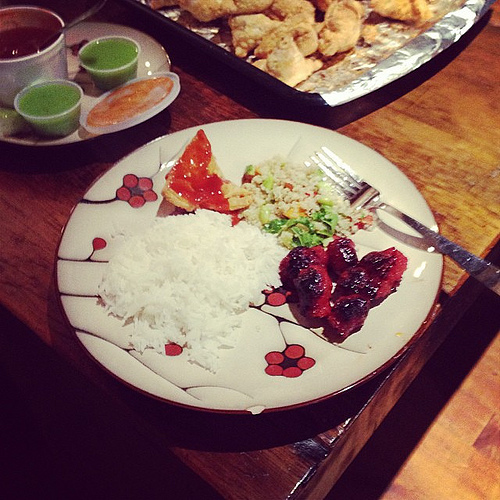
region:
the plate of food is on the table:
[39, 120, 446, 426]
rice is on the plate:
[98, 218, 264, 333]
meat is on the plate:
[280, 244, 405, 333]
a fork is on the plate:
[297, 143, 495, 284]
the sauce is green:
[7, 72, 80, 143]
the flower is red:
[249, 338, 319, 383]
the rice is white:
[110, 199, 267, 348]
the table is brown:
[430, 99, 487, 182]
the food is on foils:
[263, 45, 417, 102]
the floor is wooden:
[416, 420, 483, 488]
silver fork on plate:
[311, 150, 498, 266]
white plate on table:
[60, 126, 446, 429]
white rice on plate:
[100, 219, 268, 344]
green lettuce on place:
[262, 164, 339, 244]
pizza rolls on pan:
[249, 39, 324, 90]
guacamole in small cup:
[11, 80, 85, 138]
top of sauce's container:
[86, 74, 183, 138]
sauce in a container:
[0, 6, 69, 78]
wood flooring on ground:
[416, 365, 498, 497]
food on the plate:
[129, 150, 389, 364]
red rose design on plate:
[104, 175, 161, 210]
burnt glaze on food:
[287, 244, 315, 306]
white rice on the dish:
[141, 229, 256, 363]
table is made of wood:
[251, 384, 388, 499]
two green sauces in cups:
[21, 33, 145, 110]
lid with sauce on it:
[85, 81, 181, 129]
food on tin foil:
[218, 0, 439, 48]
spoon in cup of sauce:
[21, 5, 105, 57]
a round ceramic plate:
[54, 117, 444, 414]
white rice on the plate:
[97, 208, 289, 373]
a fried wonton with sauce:
[160, 128, 252, 213]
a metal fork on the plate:
[303, 145, 498, 294]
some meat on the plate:
[277, 235, 407, 337]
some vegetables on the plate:
[245, 153, 369, 248]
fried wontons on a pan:
[147, 0, 432, 86]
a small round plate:
[0, 20, 171, 145]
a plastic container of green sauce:
[12, 78, 84, 138]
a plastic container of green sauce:
[77, 34, 141, 89]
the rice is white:
[122, 224, 294, 350]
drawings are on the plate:
[261, 340, 329, 393]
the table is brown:
[441, 157, 493, 222]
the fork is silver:
[309, 140, 486, 276]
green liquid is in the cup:
[24, 78, 84, 145]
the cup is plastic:
[79, 38, 151, 73]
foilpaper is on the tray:
[359, 45, 442, 88]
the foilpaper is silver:
[351, 46, 443, 87]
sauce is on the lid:
[99, 79, 172, 125]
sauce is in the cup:
[16, 15, 46, 47]